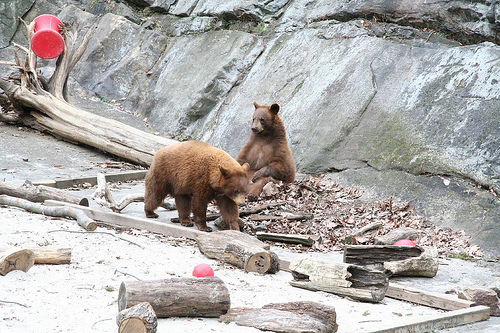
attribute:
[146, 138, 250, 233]
bear — brown, walking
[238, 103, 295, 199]
bear — brown, sitting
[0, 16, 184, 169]
log — large, down, grey, torn, dry, fallen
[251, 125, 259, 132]
nose — black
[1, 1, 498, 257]
wall — rock, grey, stone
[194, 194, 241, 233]
front legs — brown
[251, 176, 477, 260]
leaves — dead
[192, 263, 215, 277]
ball — red, blocked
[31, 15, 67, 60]
basket — red, plastic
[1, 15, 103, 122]
branches — bare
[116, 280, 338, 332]
pieces of wood — scattered